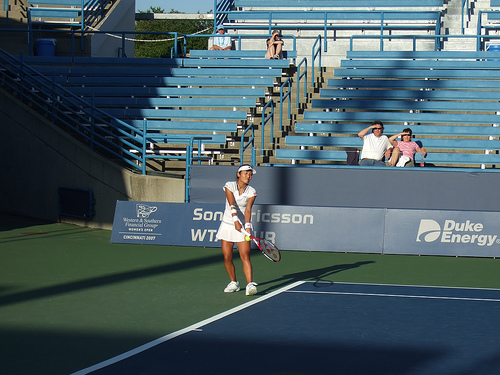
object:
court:
[4, 217, 495, 373]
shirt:
[395, 141, 420, 159]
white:
[196, 208, 202, 211]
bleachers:
[264, 36, 498, 182]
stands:
[403, 56, 488, 114]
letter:
[206, 229, 219, 243]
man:
[352, 0, 392, 56]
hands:
[373, 0, 414, 22]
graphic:
[136, 204, 158, 219]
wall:
[109, 200, 500, 256]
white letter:
[474, 220, 485, 232]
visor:
[238, 165, 257, 174]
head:
[237, 164, 254, 185]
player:
[215, 164, 257, 295]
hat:
[217, 24, 225, 30]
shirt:
[213, 32, 231, 49]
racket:
[240, 228, 281, 262]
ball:
[245, 236, 251, 242]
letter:
[455, 223, 465, 232]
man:
[358, 120, 393, 169]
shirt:
[360, 133, 393, 159]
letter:
[440, 232, 498, 247]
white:
[454, 221, 465, 231]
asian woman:
[216, 164, 257, 295]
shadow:
[254, 260, 378, 296]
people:
[389, 128, 426, 168]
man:
[210, 25, 232, 59]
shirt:
[267, 37, 280, 46]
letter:
[192, 206, 203, 222]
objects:
[232, 215, 239, 223]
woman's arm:
[224, 185, 238, 224]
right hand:
[368, 126, 381, 129]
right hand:
[399, 133, 410, 135]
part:
[225, 319, 500, 375]